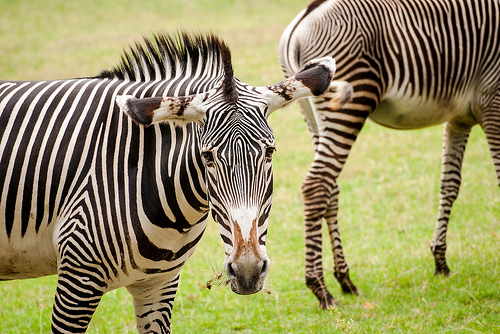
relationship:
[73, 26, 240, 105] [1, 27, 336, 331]
hair on zebra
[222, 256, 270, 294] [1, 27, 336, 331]
nose on zebra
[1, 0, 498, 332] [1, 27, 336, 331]
grass behind zebra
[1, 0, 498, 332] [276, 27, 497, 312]
grass behind zebra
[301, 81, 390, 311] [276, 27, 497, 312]
legs on zebra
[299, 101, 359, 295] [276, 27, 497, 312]
legs on zebra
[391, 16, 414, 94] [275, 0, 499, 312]
stripe on zebra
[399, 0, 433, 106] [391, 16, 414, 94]
stripe on stripe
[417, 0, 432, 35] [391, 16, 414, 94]
stripe on stripe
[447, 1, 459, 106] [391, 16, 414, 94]
stripe on stripe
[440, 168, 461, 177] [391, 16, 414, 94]
stripe on stripe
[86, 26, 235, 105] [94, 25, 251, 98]
hair on zebra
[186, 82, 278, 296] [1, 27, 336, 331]
face on zebra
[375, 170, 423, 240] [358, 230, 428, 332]
weeds in grass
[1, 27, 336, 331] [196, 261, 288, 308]
zebra grazing for food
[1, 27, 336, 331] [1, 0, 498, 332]
zebra chewing grass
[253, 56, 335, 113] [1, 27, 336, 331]
ear on zebra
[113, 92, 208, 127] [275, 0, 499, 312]
ear on zebra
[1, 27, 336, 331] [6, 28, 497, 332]
zebra in field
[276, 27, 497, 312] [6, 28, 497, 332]
zebra in field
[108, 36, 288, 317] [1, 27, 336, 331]
view of zebra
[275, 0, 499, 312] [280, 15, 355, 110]
zebra has tail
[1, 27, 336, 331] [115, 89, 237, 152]
zebra has ear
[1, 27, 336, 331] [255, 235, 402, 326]
zebra looking at camera